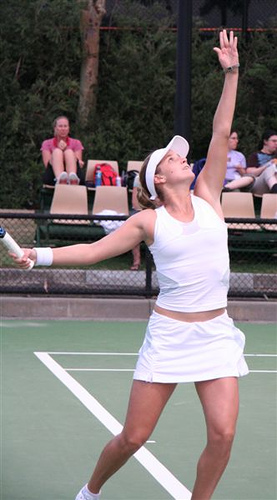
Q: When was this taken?
A: Daytime.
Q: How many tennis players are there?
A: 1.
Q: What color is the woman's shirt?
A: White.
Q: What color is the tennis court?
A: Green.